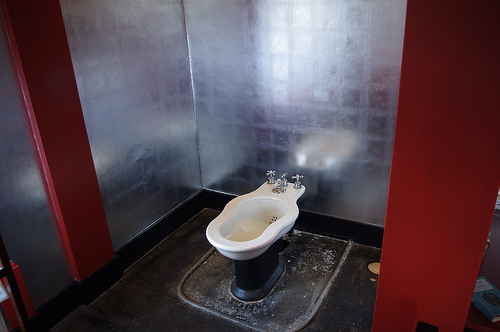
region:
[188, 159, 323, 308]
a toilet in the bathroom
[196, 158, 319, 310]
toilet is white and black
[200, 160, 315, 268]
upper piece of toilet is white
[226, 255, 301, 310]
base of toilet is black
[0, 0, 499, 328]
a walls of bathroom are gray and red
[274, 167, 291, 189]
faucet of a toilet color silver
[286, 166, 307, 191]
right handle of toilet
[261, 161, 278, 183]
left handle of toilet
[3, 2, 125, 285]
a red plank on a wall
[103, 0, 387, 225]
wall of bathroom is gray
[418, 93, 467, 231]
Medium section of red board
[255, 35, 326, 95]
Gray square-shaped wall in bathroom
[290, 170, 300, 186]
Right sink faucet in bathroom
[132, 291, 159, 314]
Brown floor in bathroom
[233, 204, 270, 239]
White part of the sink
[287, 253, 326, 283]
Dirty ground underneath the sink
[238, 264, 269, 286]
Black mid-section of the sink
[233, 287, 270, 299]
Silver bottom section of sink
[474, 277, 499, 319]
Book on the ground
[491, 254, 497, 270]
Wooden floor in next room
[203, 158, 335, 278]
the toilet is white in color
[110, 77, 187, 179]
the wall is silver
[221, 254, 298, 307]
the base of the toilet is black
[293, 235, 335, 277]
the floor has white specks on it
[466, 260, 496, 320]
the book is blue black and white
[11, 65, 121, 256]
the beam on the wall is red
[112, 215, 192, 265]
the baseboard is black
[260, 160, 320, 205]
the faucets are silver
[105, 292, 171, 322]
the floor is blackish brown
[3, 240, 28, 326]
the pipe is black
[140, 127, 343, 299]
a bidet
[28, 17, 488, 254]
a bidet in a modern bathroom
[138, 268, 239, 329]
a dirty black floor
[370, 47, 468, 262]
a red painted wall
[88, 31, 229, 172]
a wall with stainless steel paper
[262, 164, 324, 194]
knobs to control water flow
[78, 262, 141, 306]
black base boards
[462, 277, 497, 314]
a book on the floor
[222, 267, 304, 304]
a black base for an appliance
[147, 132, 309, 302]
a white porcelain bidet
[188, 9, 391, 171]
a silver metallic wall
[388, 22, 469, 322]
a red stall divider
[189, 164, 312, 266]
a short oddly shaped toilet seat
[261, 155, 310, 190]
metal knobs on the back of a toilet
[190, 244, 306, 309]
the black base of a toilet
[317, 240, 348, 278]
a metal border around a toilet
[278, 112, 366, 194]
the reflection of a toilet in the wall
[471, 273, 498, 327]
a blue and white book on the floor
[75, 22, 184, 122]
square patterns in the wall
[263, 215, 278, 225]
holes in the interior of a white toilet